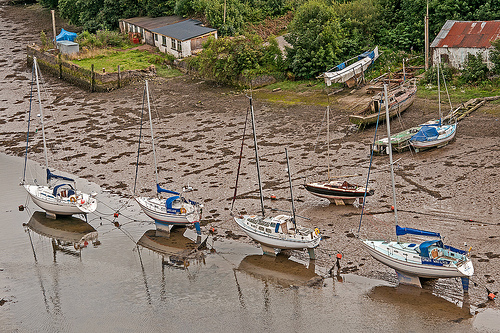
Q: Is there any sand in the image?
A: Yes, there is sand.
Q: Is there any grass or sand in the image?
A: Yes, there is sand.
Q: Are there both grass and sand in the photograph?
A: Yes, there are both sand and grass.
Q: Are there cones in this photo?
A: No, there are no cones.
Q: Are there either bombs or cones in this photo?
A: No, there are no cones or bombs.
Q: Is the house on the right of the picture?
A: Yes, the house is on the right of the image.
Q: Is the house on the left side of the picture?
A: No, the house is on the right of the image.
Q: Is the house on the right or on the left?
A: The house is on the right of the image.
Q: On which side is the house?
A: The house is on the right of the image.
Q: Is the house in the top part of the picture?
A: Yes, the house is in the top of the image.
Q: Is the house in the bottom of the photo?
A: No, the house is in the top of the image.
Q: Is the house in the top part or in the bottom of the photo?
A: The house is in the top of the image.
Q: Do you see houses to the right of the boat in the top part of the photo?
A: Yes, there is a house to the right of the boat.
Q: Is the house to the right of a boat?
A: Yes, the house is to the right of a boat.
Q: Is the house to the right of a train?
A: No, the house is to the right of a boat.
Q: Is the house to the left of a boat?
A: No, the house is to the right of a boat.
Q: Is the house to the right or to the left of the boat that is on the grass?
A: The house is to the right of the boat.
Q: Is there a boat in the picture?
A: Yes, there is a boat.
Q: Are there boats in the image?
A: Yes, there is a boat.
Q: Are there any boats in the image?
A: Yes, there is a boat.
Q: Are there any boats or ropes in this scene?
A: Yes, there is a boat.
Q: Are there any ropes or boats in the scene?
A: Yes, there is a boat.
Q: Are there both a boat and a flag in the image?
A: No, there is a boat but no flags.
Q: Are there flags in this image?
A: No, there are no flags.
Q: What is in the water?
A: The boat is in the water.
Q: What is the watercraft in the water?
A: The watercraft is a boat.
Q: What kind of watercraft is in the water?
A: The watercraft is a boat.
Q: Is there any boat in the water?
A: Yes, there is a boat in the water.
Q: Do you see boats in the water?
A: Yes, there is a boat in the water.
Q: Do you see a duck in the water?
A: No, there is a boat in the water.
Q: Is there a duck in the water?
A: No, there is a boat in the water.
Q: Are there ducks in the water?
A: No, there is a boat in the water.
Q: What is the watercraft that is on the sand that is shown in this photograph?
A: The watercraft is a boat.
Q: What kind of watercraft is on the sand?
A: The watercraft is a boat.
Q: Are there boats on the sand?
A: Yes, there is a boat on the sand.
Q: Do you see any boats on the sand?
A: Yes, there is a boat on the sand.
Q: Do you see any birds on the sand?
A: No, there is a boat on the sand.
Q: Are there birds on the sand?
A: No, there is a boat on the sand.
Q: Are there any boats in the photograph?
A: Yes, there is a boat.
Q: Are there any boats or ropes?
A: Yes, there is a boat.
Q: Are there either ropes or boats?
A: Yes, there is a boat.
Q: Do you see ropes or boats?
A: Yes, there is a boat.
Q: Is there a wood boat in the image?
A: Yes, there is a wood boat.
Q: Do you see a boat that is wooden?
A: Yes, there is a boat that is wooden.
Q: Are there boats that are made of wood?
A: Yes, there is a boat that is made of wood.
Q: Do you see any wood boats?
A: Yes, there is a boat that is made of wood.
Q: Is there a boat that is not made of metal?
A: Yes, there is a boat that is made of wood.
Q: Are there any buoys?
A: No, there are no buoys.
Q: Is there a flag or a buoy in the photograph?
A: No, there are no buoys or flags.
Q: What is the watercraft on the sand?
A: The watercraft is a boat.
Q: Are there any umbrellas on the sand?
A: No, there is a boat on the sand.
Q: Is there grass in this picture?
A: Yes, there is grass.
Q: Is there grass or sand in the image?
A: Yes, there is grass.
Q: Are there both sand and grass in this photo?
A: Yes, there are both grass and sand.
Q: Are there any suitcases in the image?
A: No, there are no suitcases.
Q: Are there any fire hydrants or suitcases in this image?
A: No, there are no suitcases or fire hydrants.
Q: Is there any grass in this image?
A: Yes, there is grass.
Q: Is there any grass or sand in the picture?
A: Yes, there is grass.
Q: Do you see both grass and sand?
A: Yes, there are both grass and sand.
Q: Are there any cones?
A: No, there are no cones.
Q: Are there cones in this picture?
A: No, there are no cones.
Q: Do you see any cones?
A: No, there are no cones.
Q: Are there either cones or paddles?
A: No, there are no cones or paddles.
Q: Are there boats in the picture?
A: Yes, there is a boat.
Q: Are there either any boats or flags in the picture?
A: Yes, there is a boat.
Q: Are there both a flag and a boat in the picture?
A: No, there is a boat but no flags.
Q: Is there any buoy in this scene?
A: No, there are no buoys.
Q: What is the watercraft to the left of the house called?
A: The watercraft is a boat.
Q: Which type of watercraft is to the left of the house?
A: The watercraft is a boat.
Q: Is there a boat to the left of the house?
A: Yes, there is a boat to the left of the house.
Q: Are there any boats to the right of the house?
A: No, the boat is to the left of the house.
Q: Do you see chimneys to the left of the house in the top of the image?
A: No, there is a boat to the left of the house.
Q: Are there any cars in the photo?
A: No, there are no cars.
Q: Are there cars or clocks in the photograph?
A: No, there are no cars or clocks.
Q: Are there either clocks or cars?
A: No, there are no cars or clocks.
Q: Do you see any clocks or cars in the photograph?
A: No, there are no cars or clocks.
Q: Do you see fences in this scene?
A: Yes, there is a fence.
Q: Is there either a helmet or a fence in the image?
A: Yes, there is a fence.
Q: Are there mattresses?
A: No, there are no mattresses.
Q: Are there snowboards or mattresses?
A: No, there are no mattresses or snowboards.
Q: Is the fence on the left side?
A: Yes, the fence is on the left of the image.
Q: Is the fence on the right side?
A: No, the fence is on the left of the image.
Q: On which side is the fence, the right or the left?
A: The fence is on the left of the image.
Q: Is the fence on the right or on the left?
A: The fence is on the left of the image.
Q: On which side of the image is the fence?
A: The fence is on the left of the image.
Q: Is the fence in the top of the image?
A: Yes, the fence is in the top of the image.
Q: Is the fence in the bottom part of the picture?
A: No, the fence is in the top of the image.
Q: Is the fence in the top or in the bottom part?
A: The fence is in the top of the image.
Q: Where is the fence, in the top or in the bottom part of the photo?
A: The fence is in the top of the image.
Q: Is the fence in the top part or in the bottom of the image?
A: The fence is in the top of the image.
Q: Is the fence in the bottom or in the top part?
A: The fence is in the top of the image.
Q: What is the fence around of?
A: The fence is around the grass.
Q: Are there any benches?
A: No, there are no benches.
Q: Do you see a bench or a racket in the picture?
A: No, there are no benches or rackets.